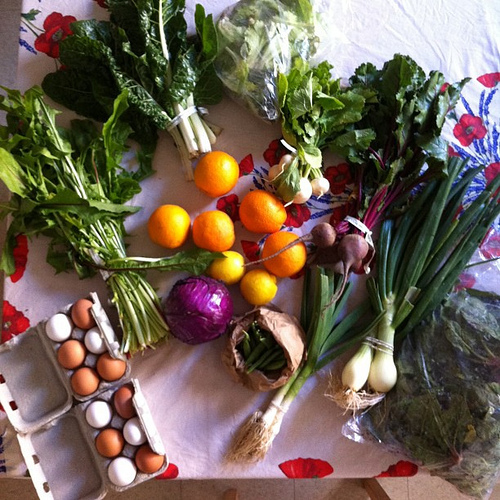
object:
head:
[161, 276, 235, 346]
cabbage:
[164, 276, 233, 346]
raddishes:
[249, 54, 377, 212]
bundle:
[279, 139, 322, 170]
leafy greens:
[0, 0, 499, 499]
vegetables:
[1, 0, 497, 500]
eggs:
[42, 297, 166, 490]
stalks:
[219, 245, 500, 469]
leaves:
[39, 0, 220, 125]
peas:
[219, 306, 306, 394]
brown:
[221, 307, 308, 393]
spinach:
[0, 85, 228, 359]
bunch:
[88, 248, 117, 282]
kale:
[38, 0, 222, 183]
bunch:
[166, 105, 210, 133]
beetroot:
[256, 51, 474, 325]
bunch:
[337, 232, 370, 275]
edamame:
[245, 345, 277, 375]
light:
[231, 0, 500, 228]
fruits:
[146, 150, 308, 308]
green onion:
[341, 156, 500, 428]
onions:
[163, 152, 499, 472]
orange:
[261, 230, 306, 278]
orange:
[191, 210, 236, 253]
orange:
[145, 204, 191, 250]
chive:
[396, 154, 463, 302]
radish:
[241, 221, 370, 313]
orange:
[238, 190, 288, 234]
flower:
[482, 73, 500, 93]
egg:
[44, 313, 72, 342]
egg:
[71, 297, 95, 329]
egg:
[56, 339, 86, 371]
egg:
[70, 367, 101, 396]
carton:
[0, 293, 169, 499]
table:
[2, 1, 498, 499]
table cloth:
[0, 0, 498, 495]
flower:
[452, 113, 487, 147]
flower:
[322, 162, 351, 194]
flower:
[3, 300, 30, 344]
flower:
[216, 192, 241, 224]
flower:
[34, 12, 78, 59]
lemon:
[208, 250, 247, 286]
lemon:
[239, 269, 278, 308]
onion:
[164, 277, 234, 346]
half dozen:
[43, 298, 127, 398]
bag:
[221, 308, 308, 393]